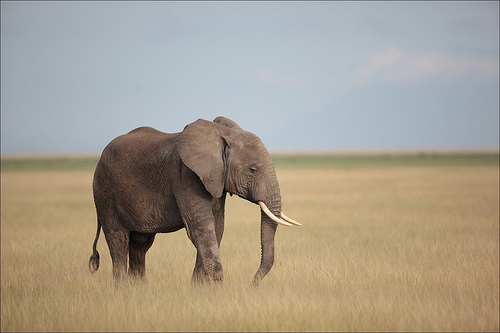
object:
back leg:
[102, 226, 129, 278]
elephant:
[88, 110, 306, 287]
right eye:
[248, 160, 258, 171]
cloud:
[0, 0, 496, 157]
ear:
[177, 118, 228, 200]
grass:
[0, 164, 500, 333]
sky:
[0, 0, 500, 149]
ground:
[0, 150, 500, 333]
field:
[6, 148, 495, 329]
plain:
[0, 151, 500, 333]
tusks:
[258, 202, 302, 227]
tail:
[90, 219, 100, 273]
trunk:
[249, 175, 281, 286]